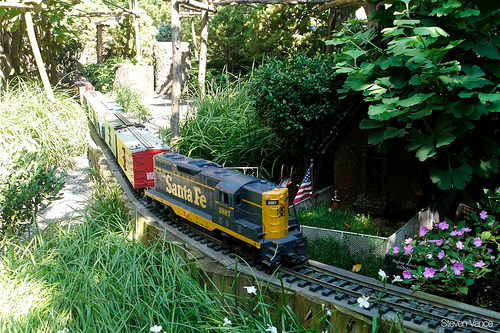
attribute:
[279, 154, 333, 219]
flag — american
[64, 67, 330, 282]
train — model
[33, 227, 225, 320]
grass — sunlit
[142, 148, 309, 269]
train — yellow, grey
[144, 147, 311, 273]
engine — yellow, grey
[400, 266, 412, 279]
flower — pink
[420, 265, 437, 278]
flower — pink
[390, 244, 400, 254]
flower — pink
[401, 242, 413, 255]
flower — pink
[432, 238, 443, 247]
flower — pink